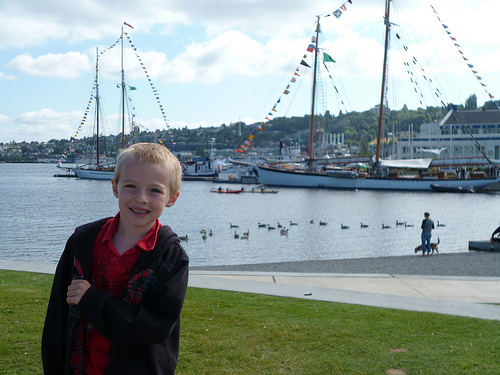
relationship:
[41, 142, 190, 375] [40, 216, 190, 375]
boy wearing coat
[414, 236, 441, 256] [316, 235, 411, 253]
dog near water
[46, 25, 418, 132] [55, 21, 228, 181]
banners on boat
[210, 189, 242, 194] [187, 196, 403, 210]
boat in water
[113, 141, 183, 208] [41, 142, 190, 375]
hair of boy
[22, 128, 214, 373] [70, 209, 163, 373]
boy wearing shirt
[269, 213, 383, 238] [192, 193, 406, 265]
ducks in water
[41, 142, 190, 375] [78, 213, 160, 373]
boy wearing shirt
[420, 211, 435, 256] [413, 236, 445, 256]
man holding dog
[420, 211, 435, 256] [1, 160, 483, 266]
man standing next to water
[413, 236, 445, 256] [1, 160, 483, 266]
dog standing next to water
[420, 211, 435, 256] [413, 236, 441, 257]
man holding dog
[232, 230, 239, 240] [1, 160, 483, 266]
bird swimming in water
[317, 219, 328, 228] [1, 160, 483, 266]
bird swimming in water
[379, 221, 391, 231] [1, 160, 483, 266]
bird swimming in water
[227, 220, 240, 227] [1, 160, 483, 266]
bird swimming in water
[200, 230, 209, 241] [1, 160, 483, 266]
bird swimming in water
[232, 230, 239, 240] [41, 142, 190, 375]
bird swimming close to boy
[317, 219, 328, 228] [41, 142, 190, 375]
bird swimming close to boy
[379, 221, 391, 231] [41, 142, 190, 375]
bird swimming close to boy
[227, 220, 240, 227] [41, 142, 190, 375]
bird swimming close to boy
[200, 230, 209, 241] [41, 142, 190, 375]
bird swimming close to boy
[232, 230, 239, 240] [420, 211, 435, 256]
bird swimming close to man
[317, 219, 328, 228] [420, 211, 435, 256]
bird swimming close to man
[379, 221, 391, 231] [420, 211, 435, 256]
bird swimming close to man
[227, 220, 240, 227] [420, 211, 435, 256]
bird swimming close to man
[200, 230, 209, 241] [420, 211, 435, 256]
bird swimming close to man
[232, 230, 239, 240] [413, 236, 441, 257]
bird swimming close to dog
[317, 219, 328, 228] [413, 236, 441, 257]
bird swimming close to dog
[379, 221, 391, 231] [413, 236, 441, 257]
bird swimming close to dog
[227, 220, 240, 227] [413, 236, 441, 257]
bird swimming close to dog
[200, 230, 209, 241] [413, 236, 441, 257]
bird swimming close to dog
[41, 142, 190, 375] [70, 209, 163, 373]
boy wearing shirt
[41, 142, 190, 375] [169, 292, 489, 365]
boy standing next to grass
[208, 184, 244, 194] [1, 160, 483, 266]
boat sitting in water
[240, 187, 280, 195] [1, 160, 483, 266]
boat sitting in water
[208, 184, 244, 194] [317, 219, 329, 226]
boat floating behind bird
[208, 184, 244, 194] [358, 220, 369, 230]
boat floating behind bird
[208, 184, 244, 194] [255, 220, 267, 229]
boat floating behind bird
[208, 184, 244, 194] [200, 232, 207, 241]
boat floating behind bird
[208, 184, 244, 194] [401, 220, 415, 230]
boat floating behind bird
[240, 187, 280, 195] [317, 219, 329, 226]
boat floating behind bird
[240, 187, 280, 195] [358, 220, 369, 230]
boat floating behind bird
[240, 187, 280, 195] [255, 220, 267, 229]
boat floating behind bird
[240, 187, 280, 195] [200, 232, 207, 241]
boat floating behind bird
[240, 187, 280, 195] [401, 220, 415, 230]
boat floating behind bird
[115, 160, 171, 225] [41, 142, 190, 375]
face belonging to boy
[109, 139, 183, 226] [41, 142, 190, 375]
head belonging to boy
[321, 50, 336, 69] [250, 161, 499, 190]
flag flying above boat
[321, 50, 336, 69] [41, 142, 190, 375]
flag flying close to boy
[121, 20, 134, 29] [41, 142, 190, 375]
flag flying close to boy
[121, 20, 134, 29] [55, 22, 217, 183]
flag flying above boat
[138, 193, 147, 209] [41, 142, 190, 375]
nose of boy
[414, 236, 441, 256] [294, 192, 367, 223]
dog near water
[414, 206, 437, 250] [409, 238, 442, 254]
man and dog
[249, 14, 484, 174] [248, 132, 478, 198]
flags attached to boat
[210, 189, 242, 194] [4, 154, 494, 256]
boat in water